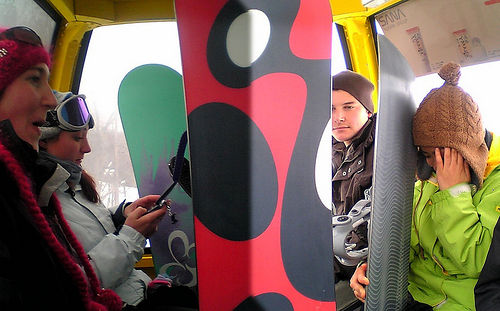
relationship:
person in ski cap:
[385, 87, 497, 307] [407, 58, 489, 190]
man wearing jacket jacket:
[330, 68, 379, 283] [326, 112, 375, 249]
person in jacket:
[385, 61, 500, 295] [388, 156, 498, 309]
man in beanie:
[330, 68, 379, 283] [330, 69, 377, 111]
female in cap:
[0, 24, 126, 310] [0, 22, 51, 69]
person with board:
[385, 61, 500, 295] [360, 33, 418, 310]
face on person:
[336, 64, 389, 160] [385, 61, 500, 295]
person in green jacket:
[385, 61, 500, 295] [407, 161, 500, 311]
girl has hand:
[37, 83, 201, 310] [127, 200, 169, 235]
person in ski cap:
[385, 61, 500, 295] [407, 58, 489, 190]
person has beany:
[385, 61, 500, 295] [409, 57, 490, 182]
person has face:
[385, 61, 500, 295] [419, 143, 464, 173]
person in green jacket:
[385, 61, 500, 295] [407, 171, 499, 301]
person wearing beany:
[385, 61, 500, 295] [409, 57, 490, 182]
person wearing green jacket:
[385, 61, 500, 295] [407, 161, 500, 311]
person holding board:
[385, 61, 500, 295] [344, 51, 406, 293]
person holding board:
[385, 61, 500, 295] [360, 33, 418, 310]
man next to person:
[330, 68, 379, 283] [385, 61, 500, 295]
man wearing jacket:
[330, 68, 379, 283] [328, 120, 378, 267]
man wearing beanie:
[330, 68, 379, 283] [302, 60, 390, 110]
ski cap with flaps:
[407, 58, 484, 190] [452, 135, 491, 185]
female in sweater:
[0, 24, 126, 310] [3, 147, 128, 306]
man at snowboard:
[330, 68, 375, 222] [176, 0, 336, 309]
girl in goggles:
[37, 83, 201, 310] [36, 92, 99, 141]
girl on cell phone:
[37, 79, 180, 309] [137, 181, 179, 217]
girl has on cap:
[37, 83, 201, 310] [0, 22, 51, 94]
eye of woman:
[23, 70, 51, 92] [269, 59, 441, 283]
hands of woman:
[114, 188, 179, 236] [41, 94, 171, 295]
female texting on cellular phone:
[0, 21, 96, 306] [145, 179, 182, 216]